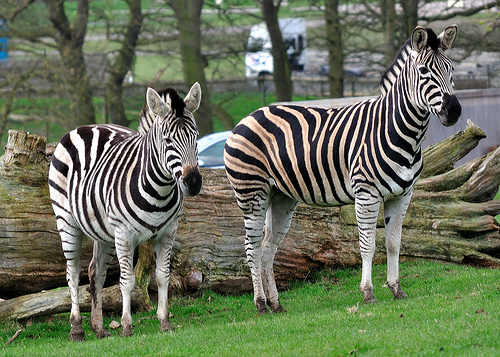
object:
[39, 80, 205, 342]
zebra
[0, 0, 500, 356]
zoo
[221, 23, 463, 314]
zebra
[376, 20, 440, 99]
mane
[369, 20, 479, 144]
head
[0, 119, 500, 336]
tree trunk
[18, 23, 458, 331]
image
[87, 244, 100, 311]
tail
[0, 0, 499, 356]
grass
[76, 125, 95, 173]
stripes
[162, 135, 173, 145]
eye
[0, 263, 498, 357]
yard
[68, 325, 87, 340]
hoof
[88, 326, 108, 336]
hoof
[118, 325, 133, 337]
hoof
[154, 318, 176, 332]
hoof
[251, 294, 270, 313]
hoof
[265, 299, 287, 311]
hoof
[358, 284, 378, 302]
hoof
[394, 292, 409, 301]
hoof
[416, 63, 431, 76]
right eye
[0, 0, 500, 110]
trees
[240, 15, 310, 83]
vehicles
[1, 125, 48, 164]
stump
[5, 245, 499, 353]
ground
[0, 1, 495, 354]
scene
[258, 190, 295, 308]
leg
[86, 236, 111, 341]
leg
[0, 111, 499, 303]
log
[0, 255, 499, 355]
patch